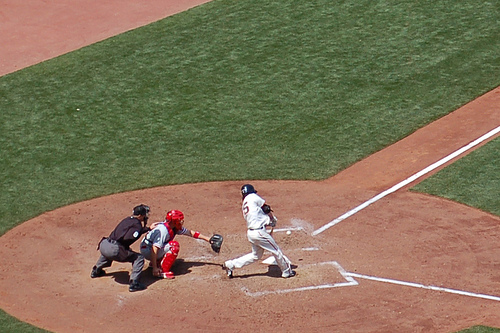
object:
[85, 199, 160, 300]
umpire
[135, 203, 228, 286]
player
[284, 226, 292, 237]
ball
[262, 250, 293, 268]
plate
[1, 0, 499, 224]
grass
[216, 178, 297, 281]
batter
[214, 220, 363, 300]
box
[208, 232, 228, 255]
mitt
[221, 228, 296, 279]
pants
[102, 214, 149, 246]
shirt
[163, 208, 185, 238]
helmet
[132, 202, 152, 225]
mask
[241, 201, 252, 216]
five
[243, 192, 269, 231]
shirt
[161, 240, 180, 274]
guards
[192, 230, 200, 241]
band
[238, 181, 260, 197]
helmet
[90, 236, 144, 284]
pants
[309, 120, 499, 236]
line